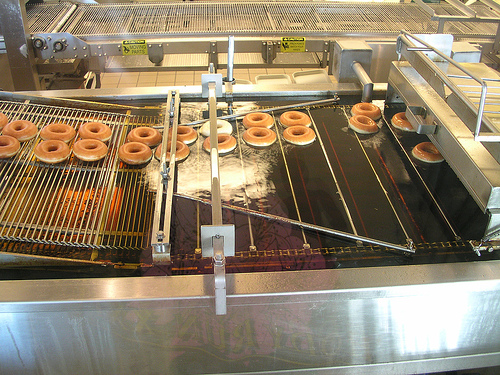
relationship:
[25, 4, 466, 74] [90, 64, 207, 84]
equipment under bad floor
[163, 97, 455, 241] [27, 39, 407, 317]
donuts in oven